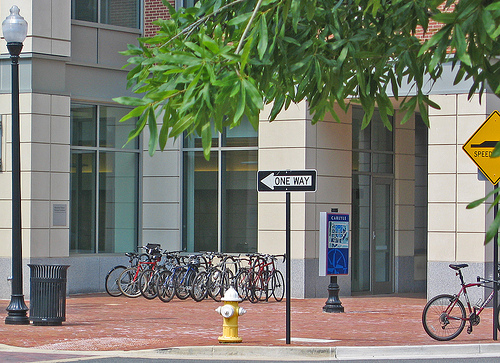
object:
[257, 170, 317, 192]
sign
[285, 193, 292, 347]
pole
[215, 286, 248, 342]
hydrant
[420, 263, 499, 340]
bike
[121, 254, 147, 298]
bike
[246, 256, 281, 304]
bike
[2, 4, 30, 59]
light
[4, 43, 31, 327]
pole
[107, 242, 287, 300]
group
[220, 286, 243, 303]
top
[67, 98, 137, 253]
windows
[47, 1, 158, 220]
building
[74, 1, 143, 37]
windows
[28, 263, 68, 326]
trashcan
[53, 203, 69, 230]
sign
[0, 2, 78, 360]
left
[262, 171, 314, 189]
arrow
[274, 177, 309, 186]
one way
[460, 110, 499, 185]
sign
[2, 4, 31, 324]
lamp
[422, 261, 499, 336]
itself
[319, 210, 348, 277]
sign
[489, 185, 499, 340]
post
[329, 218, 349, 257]
advertisement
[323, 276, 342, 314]
post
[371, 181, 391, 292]
door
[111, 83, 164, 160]
leaves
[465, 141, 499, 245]
leaves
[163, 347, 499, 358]
curb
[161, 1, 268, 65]
branch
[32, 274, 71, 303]
trash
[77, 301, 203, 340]
pavement